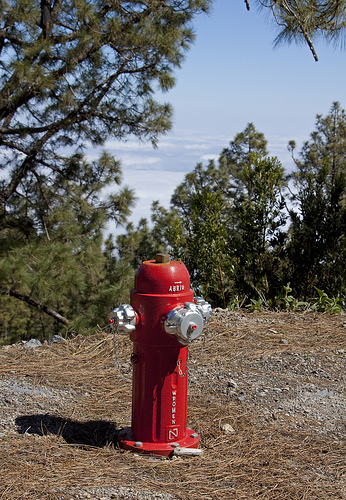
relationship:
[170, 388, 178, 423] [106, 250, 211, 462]
white words on fire hydrant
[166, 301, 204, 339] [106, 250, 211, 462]
knob on fire hydrant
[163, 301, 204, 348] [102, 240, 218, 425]
knob on hydrant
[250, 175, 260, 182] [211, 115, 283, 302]
leaves on tree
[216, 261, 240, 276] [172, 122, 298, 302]
leaves on tree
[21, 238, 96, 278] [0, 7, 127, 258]
green leaves on tree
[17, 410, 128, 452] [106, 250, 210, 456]
shadow of fire hydrant